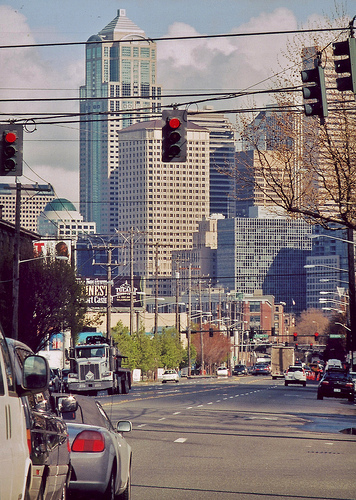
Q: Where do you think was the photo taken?
A: It was taken at the city.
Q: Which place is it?
A: It is a city.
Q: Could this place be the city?
A: Yes, it is the city.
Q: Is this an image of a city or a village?
A: It is showing a city.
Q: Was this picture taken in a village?
A: No, the picture was taken in a city.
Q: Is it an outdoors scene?
A: Yes, it is outdoors.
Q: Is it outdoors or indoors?
A: It is outdoors.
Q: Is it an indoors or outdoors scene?
A: It is outdoors.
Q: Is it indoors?
A: No, it is outdoors.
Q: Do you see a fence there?
A: No, there are no fences.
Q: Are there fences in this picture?
A: No, there are no fences.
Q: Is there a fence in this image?
A: No, there are no fences.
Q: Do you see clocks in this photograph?
A: No, there are no clocks.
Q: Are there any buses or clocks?
A: No, there are no clocks or buses.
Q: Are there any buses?
A: No, there are no buses.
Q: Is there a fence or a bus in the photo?
A: No, there are no buses or fences.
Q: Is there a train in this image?
A: No, there are no trains.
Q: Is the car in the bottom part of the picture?
A: Yes, the car is in the bottom of the image.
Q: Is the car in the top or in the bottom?
A: The car is in the bottom of the image.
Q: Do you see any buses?
A: No, there are no buses.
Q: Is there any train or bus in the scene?
A: No, there are no buses or trains.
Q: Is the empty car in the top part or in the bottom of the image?
A: The car is in the bottom of the image.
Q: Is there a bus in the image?
A: No, there are no buses.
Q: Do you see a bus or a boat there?
A: No, there are no buses or boats.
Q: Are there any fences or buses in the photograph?
A: No, there are no buses or fences.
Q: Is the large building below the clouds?
A: Yes, the building is below the clouds.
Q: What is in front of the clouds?
A: The building is in front of the clouds.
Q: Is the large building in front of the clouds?
A: Yes, the building is in front of the clouds.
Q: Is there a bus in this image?
A: No, there are no buses.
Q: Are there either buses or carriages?
A: No, there are no buses or carriages.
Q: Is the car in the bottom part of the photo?
A: Yes, the car is in the bottom of the image.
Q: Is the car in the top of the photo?
A: No, the car is in the bottom of the image.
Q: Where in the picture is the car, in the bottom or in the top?
A: The car is in the bottom of the image.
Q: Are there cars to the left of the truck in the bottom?
A: Yes, there is a car to the left of the truck.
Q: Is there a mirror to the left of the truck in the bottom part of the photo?
A: No, there is a car to the left of the truck.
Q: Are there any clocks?
A: No, there are no clocks.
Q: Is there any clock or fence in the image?
A: No, there are no clocks or fences.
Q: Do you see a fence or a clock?
A: No, there are no clocks or fences.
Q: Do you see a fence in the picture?
A: No, there are no fences.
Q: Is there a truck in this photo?
A: Yes, there is a truck.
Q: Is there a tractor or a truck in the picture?
A: Yes, there is a truck.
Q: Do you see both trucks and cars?
A: Yes, there are both a truck and cars.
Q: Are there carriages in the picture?
A: No, there are no carriages.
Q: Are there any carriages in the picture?
A: No, there are no carriages.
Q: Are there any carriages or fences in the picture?
A: No, there are no carriages or fences.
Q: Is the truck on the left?
A: Yes, the truck is on the left of the image.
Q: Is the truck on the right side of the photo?
A: No, the truck is on the left of the image.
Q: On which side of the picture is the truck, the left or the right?
A: The truck is on the left of the image.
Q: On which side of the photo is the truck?
A: The truck is on the left of the image.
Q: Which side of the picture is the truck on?
A: The truck is on the left of the image.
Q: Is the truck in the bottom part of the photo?
A: Yes, the truck is in the bottom of the image.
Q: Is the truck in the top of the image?
A: No, the truck is in the bottom of the image.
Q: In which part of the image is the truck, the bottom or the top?
A: The truck is in the bottom of the image.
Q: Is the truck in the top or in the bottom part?
A: The truck is in the bottom of the image.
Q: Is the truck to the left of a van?
A: No, the truck is to the left of the car.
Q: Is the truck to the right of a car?
A: Yes, the truck is to the right of a car.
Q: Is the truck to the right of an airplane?
A: No, the truck is to the right of a car.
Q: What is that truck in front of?
A: The truck is in front of the car.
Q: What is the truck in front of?
A: The truck is in front of the car.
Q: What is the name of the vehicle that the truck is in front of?
A: The vehicle is a car.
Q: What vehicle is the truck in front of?
A: The truck is in front of the car.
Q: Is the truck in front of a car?
A: Yes, the truck is in front of a car.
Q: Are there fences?
A: No, there are no fences.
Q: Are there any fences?
A: No, there are no fences.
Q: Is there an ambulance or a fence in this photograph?
A: No, there are no fences or ambulances.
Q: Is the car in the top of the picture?
A: No, the car is in the bottom of the image.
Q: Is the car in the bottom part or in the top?
A: The car is in the bottom of the image.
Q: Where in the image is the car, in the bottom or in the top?
A: The car is in the bottom of the image.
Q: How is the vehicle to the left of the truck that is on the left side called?
A: The vehicle is a car.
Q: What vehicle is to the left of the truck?
A: The vehicle is a car.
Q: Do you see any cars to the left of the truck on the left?
A: Yes, there is a car to the left of the truck.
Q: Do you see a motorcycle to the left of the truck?
A: No, there is a car to the left of the truck.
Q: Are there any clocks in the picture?
A: No, there are no clocks.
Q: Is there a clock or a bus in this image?
A: No, there are no clocks or buses.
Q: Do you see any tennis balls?
A: No, there are no tennis balls.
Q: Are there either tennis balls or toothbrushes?
A: No, there are no tennis balls or toothbrushes.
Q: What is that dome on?
A: The dome is on the building.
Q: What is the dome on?
A: The dome is on the building.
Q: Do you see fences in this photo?
A: No, there are no fences.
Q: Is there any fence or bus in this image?
A: No, there are no fences or buses.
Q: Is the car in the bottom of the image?
A: Yes, the car is in the bottom of the image.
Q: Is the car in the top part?
A: No, the car is in the bottom of the image.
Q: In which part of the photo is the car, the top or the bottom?
A: The car is in the bottom of the image.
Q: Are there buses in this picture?
A: No, there are no buses.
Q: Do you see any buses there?
A: No, there are no buses.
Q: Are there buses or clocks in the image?
A: No, there are no buses or clocks.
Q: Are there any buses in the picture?
A: No, there are no buses.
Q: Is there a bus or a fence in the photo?
A: No, there are no buses or fences.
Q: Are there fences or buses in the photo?
A: No, there are no buses or fences.